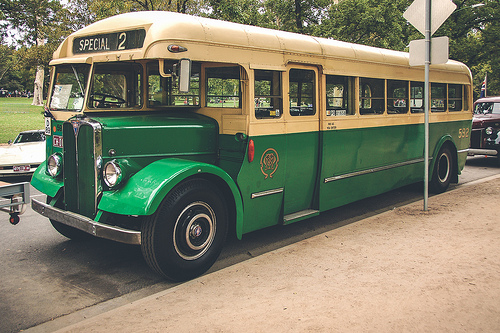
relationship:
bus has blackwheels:
[17, 20, 495, 283] [134, 180, 237, 284]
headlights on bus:
[45, 149, 120, 187] [27, 8, 473, 281]